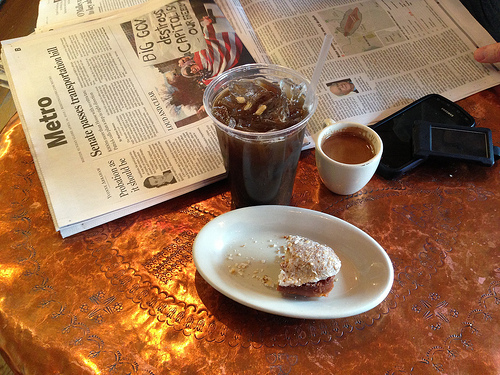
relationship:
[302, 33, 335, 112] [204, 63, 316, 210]
straw in cup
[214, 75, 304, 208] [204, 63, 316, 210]
soda in cup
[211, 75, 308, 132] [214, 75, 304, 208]
ice in soda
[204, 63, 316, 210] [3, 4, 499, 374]
cup on top of table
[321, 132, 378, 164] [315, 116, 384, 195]
coffe in cup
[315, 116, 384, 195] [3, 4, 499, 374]
cup on top of table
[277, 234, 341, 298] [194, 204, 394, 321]
muffin on plate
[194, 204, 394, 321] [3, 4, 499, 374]
plate on top of table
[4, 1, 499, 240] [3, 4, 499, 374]
newspaper on top of table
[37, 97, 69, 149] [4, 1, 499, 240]
metro on newspaper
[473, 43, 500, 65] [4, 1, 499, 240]
fingernail over newspaper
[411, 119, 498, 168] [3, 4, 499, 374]
case on top of table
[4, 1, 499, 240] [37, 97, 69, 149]
newspaper from metro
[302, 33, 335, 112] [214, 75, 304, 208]
straw in soda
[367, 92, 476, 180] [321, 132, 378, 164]
cellphone next to coffe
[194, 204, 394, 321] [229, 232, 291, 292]
plate has crumbs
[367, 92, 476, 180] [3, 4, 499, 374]
cellphone on top of table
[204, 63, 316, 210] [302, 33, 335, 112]
cup has straw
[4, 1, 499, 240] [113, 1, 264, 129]
newspaper has picture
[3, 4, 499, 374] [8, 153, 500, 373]
table has design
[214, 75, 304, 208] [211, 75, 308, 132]
soda has ice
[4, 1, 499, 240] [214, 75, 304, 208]
newspaper next to soda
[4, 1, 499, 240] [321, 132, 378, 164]
newspaper next to coffe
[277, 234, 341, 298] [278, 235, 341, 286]
muffin has top